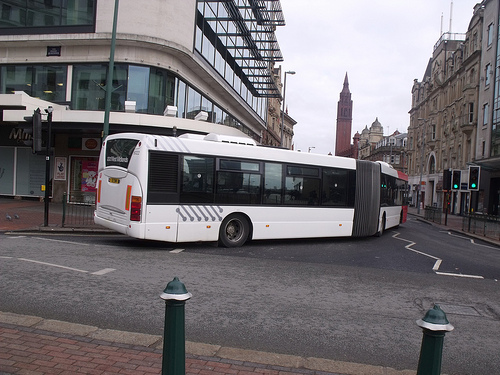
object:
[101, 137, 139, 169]
window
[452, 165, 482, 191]
signal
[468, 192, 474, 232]
pole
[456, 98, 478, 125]
window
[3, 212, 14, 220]
birds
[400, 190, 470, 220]
fence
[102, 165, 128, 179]
plate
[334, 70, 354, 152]
skyscraper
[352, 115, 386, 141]
roof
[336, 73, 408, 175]
building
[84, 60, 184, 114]
window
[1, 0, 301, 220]
building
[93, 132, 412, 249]
bus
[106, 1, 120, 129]
pole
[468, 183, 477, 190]
light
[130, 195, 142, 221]
back light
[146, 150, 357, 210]
windows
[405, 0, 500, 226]
building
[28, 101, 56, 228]
traffic light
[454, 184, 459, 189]
lights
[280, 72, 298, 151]
street light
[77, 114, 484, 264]
corner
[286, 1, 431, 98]
sky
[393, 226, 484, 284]
line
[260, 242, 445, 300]
ground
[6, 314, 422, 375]
bricks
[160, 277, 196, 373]
pole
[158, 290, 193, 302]
reflective strips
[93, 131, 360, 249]
second segment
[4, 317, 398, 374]
city sidewalk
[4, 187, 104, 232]
city sidewalk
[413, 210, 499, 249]
city sidewalk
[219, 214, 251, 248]
bus tire